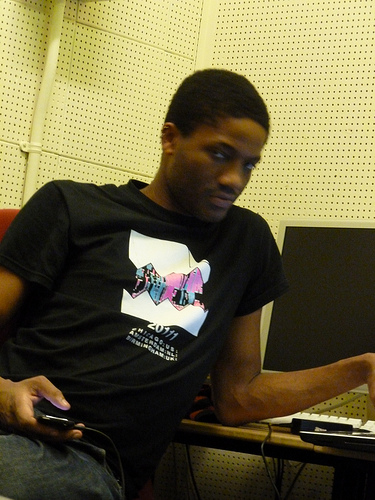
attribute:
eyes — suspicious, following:
[210, 141, 253, 173]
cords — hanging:
[181, 437, 204, 497]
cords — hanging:
[252, 421, 276, 499]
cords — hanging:
[273, 461, 288, 494]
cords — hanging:
[285, 464, 301, 494]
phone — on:
[29, 403, 78, 433]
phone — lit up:
[32, 390, 80, 433]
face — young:
[164, 120, 266, 221]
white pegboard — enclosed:
[0, 4, 373, 242]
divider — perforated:
[3, 0, 374, 234]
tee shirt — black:
[2, 175, 290, 440]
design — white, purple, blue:
[119, 227, 215, 337]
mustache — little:
[212, 185, 235, 194]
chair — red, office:
[0, 205, 26, 235]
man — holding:
[1, 67, 372, 493]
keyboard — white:
[260, 410, 374, 432]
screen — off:
[280, 219, 372, 381]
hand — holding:
[0, 375, 84, 440]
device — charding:
[37, 413, 76, 426]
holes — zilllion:
[285, 17, 363, 177]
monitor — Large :
[260, 218, 373, 394]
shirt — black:
[1, 168, 284, 449]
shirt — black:
[0, 176, 289, 499]